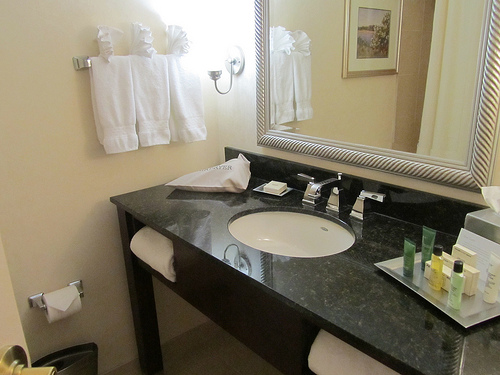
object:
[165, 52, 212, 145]
towel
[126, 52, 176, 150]
towel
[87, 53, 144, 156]
towel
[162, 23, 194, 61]
towel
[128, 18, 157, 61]
towel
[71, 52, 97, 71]
towel rack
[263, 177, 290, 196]
soap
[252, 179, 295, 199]
dish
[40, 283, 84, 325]
toilet paper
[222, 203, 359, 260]
sink